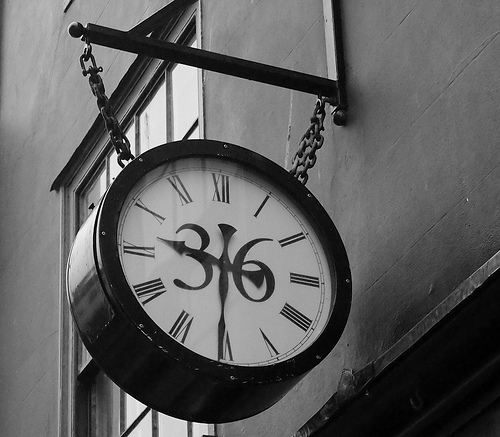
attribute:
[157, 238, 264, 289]
clock hand — black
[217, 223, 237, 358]
clock hand — black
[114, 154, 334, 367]
clock face — white, glass